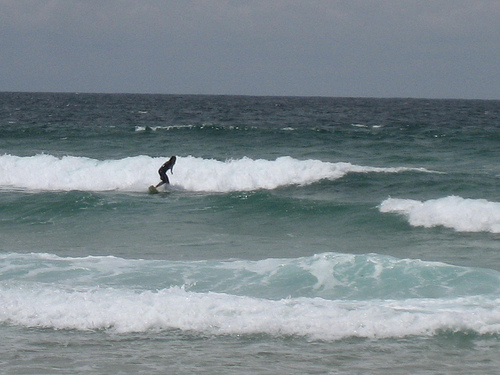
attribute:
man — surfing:
[154, 156, 187, 182]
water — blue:
[267, 109, 384, 232]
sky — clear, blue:
[229, 4, 329, 75]